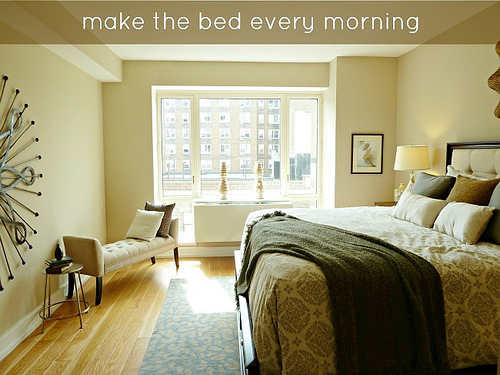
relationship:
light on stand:
[388, 133, 432, 189] [393, 202, 394, 203]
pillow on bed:
[370, 162, 480, 255] [231, 132, 492, 322]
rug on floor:
[142, 270, 237, 360] [75, 289, 151, 373]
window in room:
[145, 77, 333, 188] [50, 24, 471, 320]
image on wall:
[352, 140, 382, 172] [343, 116, 414, 198]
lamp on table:
[357, 120, 440, 214] [368, 188, 402, 209]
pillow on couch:
[370, 162, 480, 255] [95, 238, 168, 272]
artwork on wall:
[342, 133, 381, 172] [343, 116, 414, 198]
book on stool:
[43, 246, 99, 277] [27, 244, 123, 335]